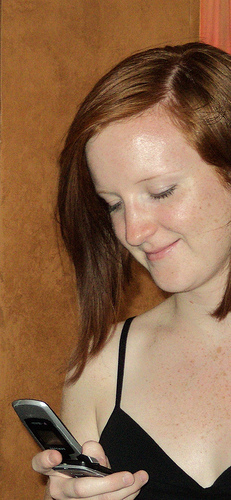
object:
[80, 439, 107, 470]
thumb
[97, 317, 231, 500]
shirt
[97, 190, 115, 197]
eyebrows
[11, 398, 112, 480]
cell phone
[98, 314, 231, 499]
dress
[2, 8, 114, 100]
wall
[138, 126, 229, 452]
freckles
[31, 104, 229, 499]
skin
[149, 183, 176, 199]
eye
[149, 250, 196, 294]
chin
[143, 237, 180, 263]
lips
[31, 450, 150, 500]
hand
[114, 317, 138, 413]
strap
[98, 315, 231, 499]
top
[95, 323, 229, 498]
chest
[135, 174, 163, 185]
eyebrow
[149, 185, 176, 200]
eyelashes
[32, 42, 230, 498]
girl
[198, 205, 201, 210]
beauty mark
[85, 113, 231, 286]
face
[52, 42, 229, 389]
hair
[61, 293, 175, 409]
shoulder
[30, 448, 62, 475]
finger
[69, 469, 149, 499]
finger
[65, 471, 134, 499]
finger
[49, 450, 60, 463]
fingernail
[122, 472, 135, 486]
fingernail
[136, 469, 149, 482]
fingernail